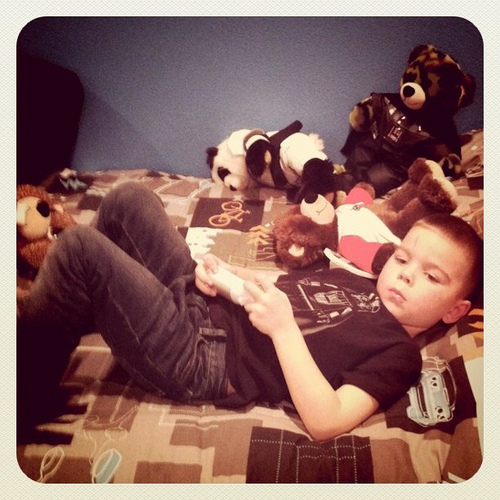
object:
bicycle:
[208, 198, 252, 229]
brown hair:
[410, 212, 482, 299]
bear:
[337, 42, 477, 197]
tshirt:
[216, 257, 421, 421]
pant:
[17, 182, 227, 414]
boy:
[15, 182, 482, 443]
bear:
[203, 118, 340, 206]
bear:
[273, 155, 459, 275]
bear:
[18, 184, 77, 269]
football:
[43, 164, 94, 196]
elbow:
[300, 409, 337, 442]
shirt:
[328, 201, 404, 276]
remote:
[197, 250, 267, 308]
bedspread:
[18, 132, 485, 482]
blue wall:
[28, 37, 316, 160]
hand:
[192, 249, 225, 300]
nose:
[402, 85, 414, 97]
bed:
[17, 122, 482, 482]